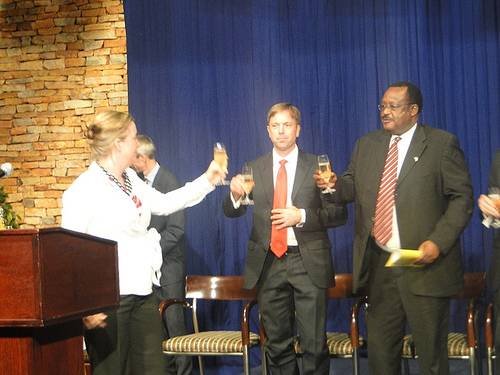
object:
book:
[383, 247, 432, 268]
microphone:
[0, 160, 15, 181]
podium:
[0, 224, 123, 330]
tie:
[268, 159, 291, 259]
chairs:
[157, 271, 258, 374]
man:
[219, 99, 348, 374]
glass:
[238, 162, 257, 206]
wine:
[241, 177, 254, 194]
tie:
[372, 134, 403, 247]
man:
[315, 79, 476, 373]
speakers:
[312, 79, 476, 374]